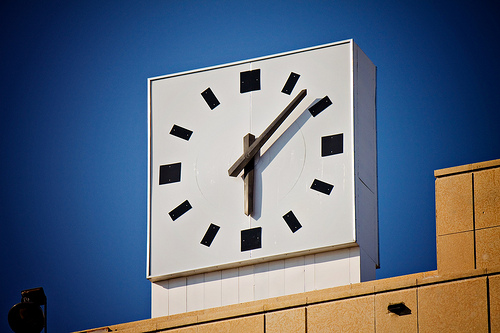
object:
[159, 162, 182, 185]
square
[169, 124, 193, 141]
square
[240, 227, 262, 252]
square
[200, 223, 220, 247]
square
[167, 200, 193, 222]
square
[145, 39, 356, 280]
clock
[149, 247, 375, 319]
clock base